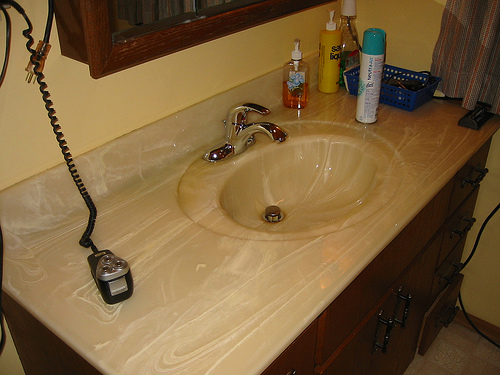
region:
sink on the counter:
[171, 85, 393, 250]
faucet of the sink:
[190, 99, 292, 156]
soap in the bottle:
[272, 41, 318, 106]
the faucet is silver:
[261, 122, 283, 141]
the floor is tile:
[463, 361, 493, 373]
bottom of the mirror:
[117, 1, 169, 33]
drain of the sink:
[265, 198, 287, 218]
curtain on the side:
[407, 0, 493, 103]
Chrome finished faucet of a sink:
[202, 101, 294, 166]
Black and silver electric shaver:
[81, 246, 136, 308]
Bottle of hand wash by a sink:
[279, 38, 309, 110]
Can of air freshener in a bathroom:
[355, 27, 385, 125]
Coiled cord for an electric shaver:
[15, 16, 114, 249]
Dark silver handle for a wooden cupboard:
[369, 308, 396, 364]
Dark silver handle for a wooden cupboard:
[395, 284, 414, 331]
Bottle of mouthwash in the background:
[337, 2, 363, 87]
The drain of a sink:
[261, 202, 284, 223]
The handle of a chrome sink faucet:
[227, 100, 273, 122]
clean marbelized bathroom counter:
[5, 10, 499, 357]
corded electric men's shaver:
[82, 229, 135, 305]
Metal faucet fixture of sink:
[202, 103, 284, 164]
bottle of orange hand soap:
[285, 36, 310, 116]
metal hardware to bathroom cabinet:
[382, 291, 421, 351]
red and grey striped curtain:
[445, 2, 495, 110]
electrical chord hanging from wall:
[22, 32, 54, 93]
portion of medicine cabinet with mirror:
[100, 0, 232, 38]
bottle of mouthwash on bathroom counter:
[336, 2, 364, 86]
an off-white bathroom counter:
[1, 40, 496, 374]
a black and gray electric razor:
[85, 248, 134, 305]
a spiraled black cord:
[21, 24, 100, 252]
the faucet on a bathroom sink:
[205, 99, 287, 164]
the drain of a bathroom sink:
[260, 202, 285, 224]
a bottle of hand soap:
[281, 34, 307, 120]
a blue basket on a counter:
[338, 57, 444, 110]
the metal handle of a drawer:
[462, 162, 493, 192]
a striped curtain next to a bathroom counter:
[427, 1, 498, 115]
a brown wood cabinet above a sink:
[53, 0, 343, 78]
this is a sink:
[168, 90, 403, 257]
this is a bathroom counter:
[60, 2, 477, 343]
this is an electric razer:
[45, 170, 172, 362]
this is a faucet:
[191, 73, 311, 180]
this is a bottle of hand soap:
[276, 30, 340, 145]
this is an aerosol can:
[357, 28, 396, 124]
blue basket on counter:
[337, 47, 434, 113]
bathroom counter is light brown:
[48, 40, 485, 344]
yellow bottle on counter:
[310, 15, 352, 122]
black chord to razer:
[8, 14, 123, 256]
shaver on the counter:
[5, 9, 156, 317]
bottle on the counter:
[273, 31, 319, 126]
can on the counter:
[351, 14, 390, 125]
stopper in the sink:
[257, 198, 288, 225]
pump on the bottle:
[283, 33, 309, 62]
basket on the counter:
[345, 55, 434, 112]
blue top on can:
[357, 20, 387, 60]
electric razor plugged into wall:
[5, 0, 134, 302]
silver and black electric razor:
[5, 0, 134, 303]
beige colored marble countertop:
[0, 52, 498, 374]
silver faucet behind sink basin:
[178, 102, 402, 239]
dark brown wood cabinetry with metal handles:
[245, 135, 493, 374]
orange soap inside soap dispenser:
[278, 35, 310, 109]